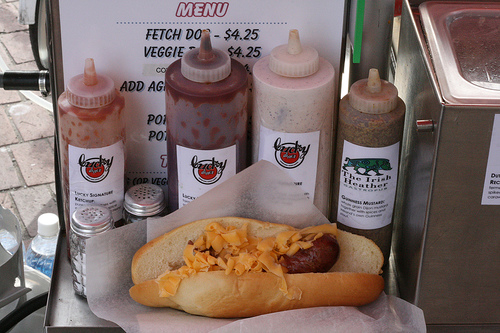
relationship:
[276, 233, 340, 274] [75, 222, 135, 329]
hot dog on a wrapper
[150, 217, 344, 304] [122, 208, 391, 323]
cheese on a hot dog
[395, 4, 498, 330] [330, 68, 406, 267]
metal box next to some bottle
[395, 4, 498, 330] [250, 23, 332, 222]
metal box next to some condiment bottle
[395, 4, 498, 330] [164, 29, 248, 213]
metal box next to some bottles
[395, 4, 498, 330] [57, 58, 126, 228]
metal box next to some bottle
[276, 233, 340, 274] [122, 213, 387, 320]
hot dog in a bun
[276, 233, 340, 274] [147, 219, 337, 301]
hot dog covered with cheese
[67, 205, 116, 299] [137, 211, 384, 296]
salt behind hotdog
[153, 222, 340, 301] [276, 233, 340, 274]
cheese on hot dog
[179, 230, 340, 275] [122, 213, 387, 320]
hot dog on bun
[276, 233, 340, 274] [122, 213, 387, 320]
hot dog sitting in bun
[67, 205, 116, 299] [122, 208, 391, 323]
salt near hot dog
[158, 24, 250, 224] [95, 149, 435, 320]
sauce near hot dog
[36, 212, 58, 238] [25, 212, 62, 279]
top on bottle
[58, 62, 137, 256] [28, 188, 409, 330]
bottle on tray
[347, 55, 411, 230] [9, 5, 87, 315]
bottle outside window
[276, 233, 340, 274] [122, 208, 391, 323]
hot dog in hot dog